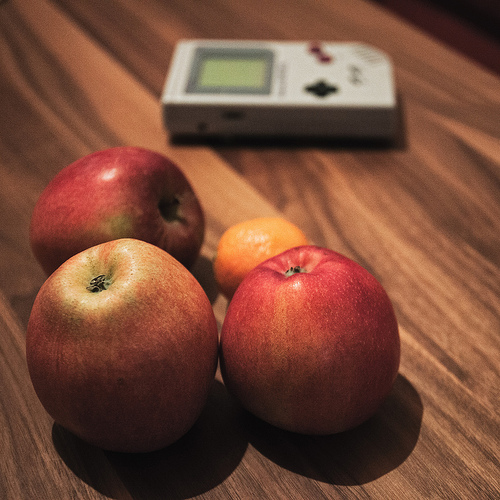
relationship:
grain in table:
[6, 92, 47, 156] [3, 1, 482, 222]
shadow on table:
[289, 433, 386, 482] [3, 1, 482, 222]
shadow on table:
[74, 457, 203, 499] [3, 1, 482, 222]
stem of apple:
[285, 265, 305, 274] [235, 245, 401, 435]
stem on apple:
[85, 275, 120, 293] [14, 245, 220, 456]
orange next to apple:
[219, 216, 314, 263] [24, 149, 211, 260]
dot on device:
[308, 44, 331, 67] [162, 38, 400, 142]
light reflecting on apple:
[101, 164, 120, 183] [24, 149, 211, 260]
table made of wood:
[3, 1, 482, 222] [431, 52, 471, 93]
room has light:
[6, 5, 498, 496] [101, 164, 120, 183]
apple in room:
[235, 245, 401, 435] [6, 5, 498, 496]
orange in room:
[219, 216, 314, 263] [6, 5, 498, 496]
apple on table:
[25, 237, 220, 455] [3, 1, 482, 222]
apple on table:
[24, 149, 211, 260] [3, 1, 482, 222]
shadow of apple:
[289, 433, 386, 482] [235, 245, 401, 435]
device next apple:
[162, 38, 400, 142] [25, 237, 220, 455]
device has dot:
[162, 38, 400, 142] [308, 44, 331, 67]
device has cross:
[162, 38, 400, 142] [304, 79, 341, 102]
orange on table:
[219, 216, 314, 263] [3, 1, 482, 222]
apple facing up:
[235, 245, 401, 435] [134, 12, 195, 25]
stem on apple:
[285, 265, 305, 274] [235, 245, 401, 435]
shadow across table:
[289, 433, 386, 482] [3, 1, 482, 222]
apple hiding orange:
[24, 149, 211, 260] [219, 216, 314, 263]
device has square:
[162, 38, 400, 142] [200, 49, 266, 95]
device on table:
[162, 38, 400, 142] [3, 1, 482, 222]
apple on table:
[235, 245, 401, 435] [3, 1, 482, 222]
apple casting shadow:
[235, 245, 401, 435] [289, 433, 386, 482]